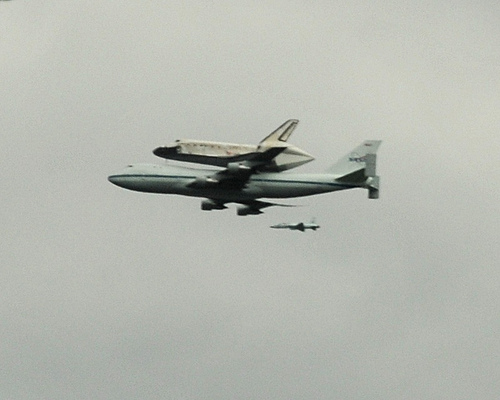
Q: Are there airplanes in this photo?
A: Yes, there is an airplane.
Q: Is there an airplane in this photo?
A: Yes, there is an airplane.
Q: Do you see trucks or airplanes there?
A: Yes, there is an airplane.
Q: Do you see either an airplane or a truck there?
A: Yes, there is an airplane.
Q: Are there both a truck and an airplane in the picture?
A: No, there is an airplane but no trucks.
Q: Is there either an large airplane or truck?
A: Yes, there is a large airplane.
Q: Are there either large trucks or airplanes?
A: Yes, there is a large airplane.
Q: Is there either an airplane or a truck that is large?
A: Yes, the airplane is large.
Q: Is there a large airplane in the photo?
A: Yes, there is a large airplane.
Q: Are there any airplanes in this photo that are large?
A: Yes, there is an airplane that is large.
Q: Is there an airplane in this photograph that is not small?
A: Yes, there is a large airplane.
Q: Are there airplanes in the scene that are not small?
A: Yes, there is a large airplane.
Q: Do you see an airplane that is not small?
A: Yes, there is a large airplane.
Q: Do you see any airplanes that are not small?
A: Yes, there is a large airplane.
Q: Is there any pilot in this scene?
A: No, there are no pilots.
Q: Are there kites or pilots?
A: No, there are no pilots or kites.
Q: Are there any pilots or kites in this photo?
A: No, there are no pilots or kites.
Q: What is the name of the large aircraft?
A: The aircraft is an airplane.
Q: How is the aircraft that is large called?
A: The aircraft is an airplane.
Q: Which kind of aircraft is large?
A: The aircraft is an airplane.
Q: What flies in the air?
A: The airplane flies in the air.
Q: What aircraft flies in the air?
A: The aircraft is an airplane.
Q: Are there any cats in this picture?
A: No, there are no cats.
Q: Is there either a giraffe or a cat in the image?
A: No, there are no cats or giraffes.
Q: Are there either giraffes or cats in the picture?
A: No, there are no cats or giraffes.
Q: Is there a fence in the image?
A: No, there are no fences.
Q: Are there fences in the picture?
A: No, there are no fences.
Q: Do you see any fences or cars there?
A: No, there are no fences or cars.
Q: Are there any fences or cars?
A: No, there are no fences or cars.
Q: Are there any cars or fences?
A: No, there are no fences or cars.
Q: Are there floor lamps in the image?
A: No, there are no floor lamps.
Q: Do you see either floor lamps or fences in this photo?
A: No, there are no floor lamps or fences.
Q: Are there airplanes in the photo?
A: Yes, there are airplanes.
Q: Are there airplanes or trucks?
A: Yes, there are airplanes.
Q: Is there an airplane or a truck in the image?
A: Yes, there are airplanes.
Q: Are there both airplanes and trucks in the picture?
A: No, there are airplanes but no trucks.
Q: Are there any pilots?
A: No, there are no pilots.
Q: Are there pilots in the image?
A: No, there are no pilots.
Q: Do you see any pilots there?
A: No, there are no pilots.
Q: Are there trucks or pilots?
A: No, there are no pilots or trucks.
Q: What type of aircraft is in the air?
A: The aircraft is airplanes.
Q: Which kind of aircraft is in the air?
A: The aircraft is airplanes.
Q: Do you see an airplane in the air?
A: Yes, there are airplanes in the air.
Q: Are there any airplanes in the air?
A: Yes, there are airplanes in the air.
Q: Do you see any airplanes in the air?
A: Yes, there are airplanes in the air.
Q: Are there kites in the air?
A: No, there are airplanes in the air.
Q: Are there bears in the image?
A: No, there are no bears.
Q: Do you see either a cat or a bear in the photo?
A: No, there are no bears or cats.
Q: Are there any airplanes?
A: Yes, there is an airplane.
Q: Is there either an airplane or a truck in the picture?
A: Yes, there is an airplane.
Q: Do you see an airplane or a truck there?
A: Yes, there is an airplane.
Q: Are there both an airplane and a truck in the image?
A: No, there is an airplane but no trucks.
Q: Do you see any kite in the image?
A: No, there are no kites.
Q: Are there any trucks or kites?
A: No, there are no kites or trucks.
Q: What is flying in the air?
A: The plane is flying in the air.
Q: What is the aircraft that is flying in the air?
A: The aircraft is an airplane.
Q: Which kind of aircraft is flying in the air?
A: The aircraft is an airplane.